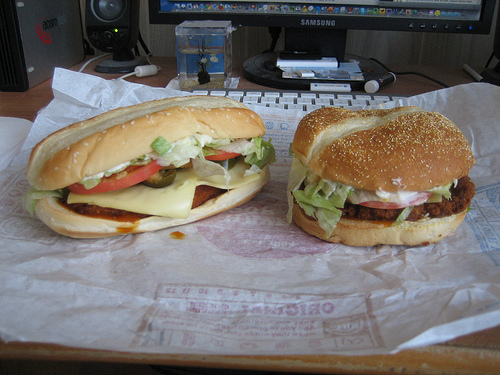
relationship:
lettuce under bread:
[303, 182, 332, 200] [289, 180, 476, 246]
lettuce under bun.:
[277, 142, 354, 228] [273, 101, 478, 259]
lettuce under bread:
[150, 135, 170, 156] [27, 94, 265, 194]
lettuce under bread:
[244, 136, 264, 159] [27, 94, 265, 194]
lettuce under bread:
[79, 175, 101, 189] [27, 94, 265, 194]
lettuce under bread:
[21, 188, 64, 215] [27, 94, 265, 194]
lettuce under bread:
[243, 154, 275, 166] [27, 94, 265, 194]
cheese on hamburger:
[63, 171, 261, 223] [14, 86, 281, 245]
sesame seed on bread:
[118, 123, 126, 129] [27, 94, 265, 194]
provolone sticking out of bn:
[303, 172, 348, 209] [288, 98, 478, 247]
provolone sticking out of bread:
[73, 188, 192, 218] [293, 106, 474, 194]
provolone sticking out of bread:
[73, 188, 192, 218] [27, 94, 265, 194]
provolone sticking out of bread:
[70, 162, 257, 215] [33, 165, 270, 240]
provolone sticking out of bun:
[73, 188, 192, 218] [27, 102, 264, 182]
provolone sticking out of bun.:
[73, 188, 192, 218] [26, 88, 274, 251]